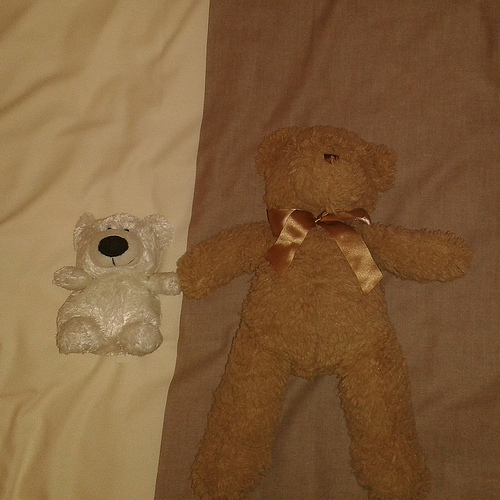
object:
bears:
[45, 125, 500, 499]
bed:
[139, 64, 223, 147]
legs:
[38, 291, 188, 374]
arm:
[376, 180, 482, 330]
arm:
[162, 180, 270, 350]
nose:
[299, 130, 353, 180]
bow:
[240, 167, 397, 319]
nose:
[310, 114, 371, 187]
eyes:
[281, 123, 412, 193]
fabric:
[198, 17, 473, 493]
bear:
[178, 86, 477, 499]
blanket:
[57, 5, 470, 458]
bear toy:
[53, 210, 179, 354]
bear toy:
[175, 125, 469, 496]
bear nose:
[95, 235, 127, 256]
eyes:
[104, 226, 131, 232]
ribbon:
[263, 205, 383, 293]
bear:
[50, 212, 180, 355]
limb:
[151, 267, 182, 286]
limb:
[117, 320, 159, 353]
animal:
[49, 201, 191, 372]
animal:
[165, 134, 483, 492]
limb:
[161, 219, 272, 312]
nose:
[97, 217, 142, 263]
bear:
[30, 138, 483, 476]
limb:
[365, 223, 466, 281]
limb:
[51, 315, 111, 359]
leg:
[163, 347, 307, 498]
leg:
[325, 332, 434, 498]